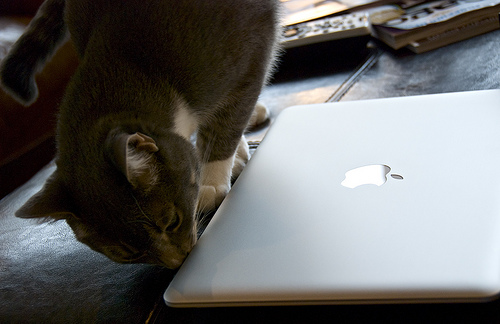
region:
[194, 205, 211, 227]
the cats whiskers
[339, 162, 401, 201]
the apple logo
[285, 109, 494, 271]
a closed laptop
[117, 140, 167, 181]
cats ear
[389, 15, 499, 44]
magazines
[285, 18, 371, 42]
a remote controller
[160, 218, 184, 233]
the cats eye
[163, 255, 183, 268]
nose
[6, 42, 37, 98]
the cats tail is grey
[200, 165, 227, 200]
the cats paws are white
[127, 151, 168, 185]
White fur inside of cat's ear.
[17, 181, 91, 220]
Cat has gray ear.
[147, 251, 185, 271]
Cat has gray nose.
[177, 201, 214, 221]
Cat has white whiskers.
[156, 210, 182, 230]
Cat has green eyes.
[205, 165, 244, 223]
Cat has white paw.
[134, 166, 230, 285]
Cat is sniffing a laptop.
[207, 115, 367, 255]
Silver apple laptop next to cat.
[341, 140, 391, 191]
Apple logo on top of laptop.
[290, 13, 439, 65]
Remote control in distance.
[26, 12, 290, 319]
the cat is sniffing the laptop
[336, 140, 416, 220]
the logo is apple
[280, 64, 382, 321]
the laptop is gray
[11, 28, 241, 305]
the cat has whiskers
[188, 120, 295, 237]
the paws are white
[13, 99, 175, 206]
the ears have hair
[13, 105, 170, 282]
the ears are gray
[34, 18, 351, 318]
the cat is gray and white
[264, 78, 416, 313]
the laptop is closed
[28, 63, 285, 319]
the cat is gray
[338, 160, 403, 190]
Apple computers logo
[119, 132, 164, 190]
Furry ear of a house cat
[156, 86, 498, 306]
Closed lap top computer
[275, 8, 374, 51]
Remote control for a tv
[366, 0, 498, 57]
Two magazine stacked atop each other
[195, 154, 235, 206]
Front paw of a house cat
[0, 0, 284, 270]
Grey and white colored cat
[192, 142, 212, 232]
Whiskers of a cat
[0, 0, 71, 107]
Tail of a house cat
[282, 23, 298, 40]
Orange button on a tv remote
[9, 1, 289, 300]
gray and white cat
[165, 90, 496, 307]
lap top computer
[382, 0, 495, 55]
a couple of magazines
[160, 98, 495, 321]
apple computer on a desk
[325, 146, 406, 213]
symbol on a computer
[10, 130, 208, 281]
cat smelling computer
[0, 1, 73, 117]
a gray color cat tail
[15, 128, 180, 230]
a pair of cat ears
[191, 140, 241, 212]
a white cat paw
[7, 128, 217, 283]
a cats head